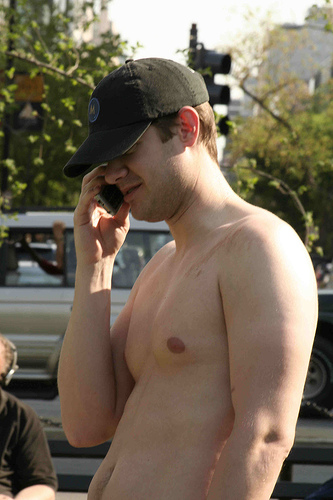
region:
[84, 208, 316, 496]
Bare torso of a man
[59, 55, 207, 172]
black baseball cap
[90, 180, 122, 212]
cell phone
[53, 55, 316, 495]
Man with a black baseball cap speaking on a cell phone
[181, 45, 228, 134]
black traffic light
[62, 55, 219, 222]
black baseball cap on the head of man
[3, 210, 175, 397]
silver vehicle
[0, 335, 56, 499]
man wearing headphones sitting down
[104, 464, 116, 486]
belly button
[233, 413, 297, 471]
elbow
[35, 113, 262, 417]
the man is naked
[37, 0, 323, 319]
the man is naked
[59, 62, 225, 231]
man wearing black hat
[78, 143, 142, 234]
man talking on cell phone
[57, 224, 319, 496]
man not wearing a shirt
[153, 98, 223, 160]
medium brown hair sticking out of hat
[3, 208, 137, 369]
silver suv behind man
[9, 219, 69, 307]
arm hanging out window of silver suv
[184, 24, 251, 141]
black painted traffic signal light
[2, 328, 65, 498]
man in black shirt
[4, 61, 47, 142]
yellow and black sign on post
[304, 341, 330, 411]
tire of vehicle behind arm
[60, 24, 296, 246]
a man wearing a hat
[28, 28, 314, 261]
a man wearing a black hat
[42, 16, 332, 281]
a man holding a cell phone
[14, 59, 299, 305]
a man holding a phone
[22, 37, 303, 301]
a man talking on a phone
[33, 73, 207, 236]
a man talking on a cell phone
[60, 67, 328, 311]
a man on the phone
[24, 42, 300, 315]
a man talking on the phone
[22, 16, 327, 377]
a man wearing no shirt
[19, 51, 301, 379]
a man wearing a hat and no shirt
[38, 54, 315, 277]
a man on phone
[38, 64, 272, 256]
a man on cell phone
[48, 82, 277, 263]
a man talking on phone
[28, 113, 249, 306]
a man talking on a cell phone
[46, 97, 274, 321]
a man on a cell phone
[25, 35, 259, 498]
a man with no shirt